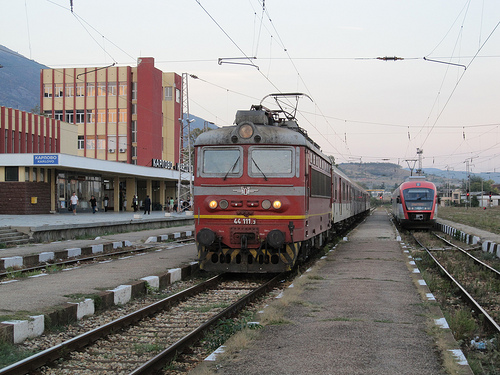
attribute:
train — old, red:
[180, 100, 371, 272]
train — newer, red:
[385, 174, 438, 229]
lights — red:
[465, 188, 471, 197]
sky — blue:
[1, 2, 498, 173]